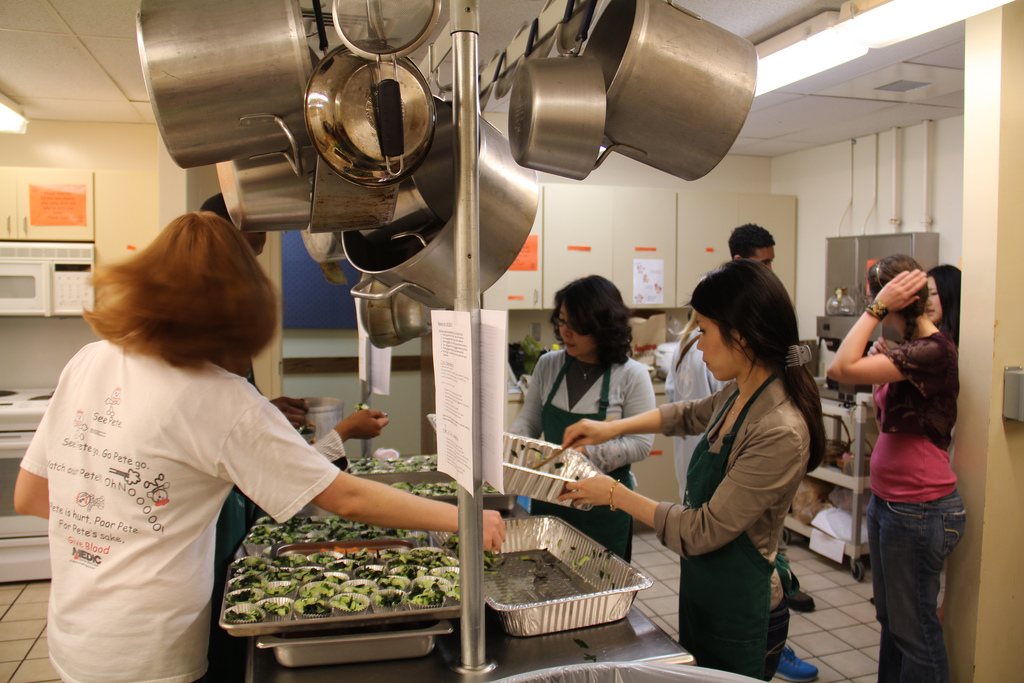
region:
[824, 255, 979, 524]
a Woman wearing a pink shirt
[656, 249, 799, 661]
A woman wearing an apron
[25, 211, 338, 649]
A woman wearing a white T-shirt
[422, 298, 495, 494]
directions on how to make lunch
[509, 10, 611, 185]
A pot hanging from the ceiling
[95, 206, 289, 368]
a woman with reddish hair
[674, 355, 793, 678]
Girl wearing an apron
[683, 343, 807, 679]
Girl is wearing an apron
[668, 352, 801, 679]
Girl wearing a green apron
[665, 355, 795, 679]
Girl is wearing a green apron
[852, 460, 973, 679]
Girl wearing pants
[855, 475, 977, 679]
Girl is wearing blue pants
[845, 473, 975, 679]
Girl wearing blue jeans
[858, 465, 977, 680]
Girl is wearing blue jeans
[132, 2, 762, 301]
pots hanging from the ceiling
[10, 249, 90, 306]
a white microwave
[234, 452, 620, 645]
food on the table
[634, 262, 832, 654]
a lady in a brown shirt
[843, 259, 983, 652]
a lady standing by the wall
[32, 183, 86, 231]
an orange paper on the wall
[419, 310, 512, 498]
papers hanging from the pole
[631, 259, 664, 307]
a white paper on the wall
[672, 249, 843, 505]
lady with long hair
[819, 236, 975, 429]
lady with hand on head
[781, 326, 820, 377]
a grey hair clip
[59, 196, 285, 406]
the hair is wild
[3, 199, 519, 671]
the person is wearing white shirt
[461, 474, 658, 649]
the pan is empty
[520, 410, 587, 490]
a spoon in a hand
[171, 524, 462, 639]
food in a pan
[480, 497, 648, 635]
Aluminum tin pan on the table.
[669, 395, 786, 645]
The lady is wearing a green apron.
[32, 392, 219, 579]
The shirt has writing on the back of it.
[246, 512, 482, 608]
Food on the cooking sheet.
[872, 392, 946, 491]
The shirt is red.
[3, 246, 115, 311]
A white microwave above the stove.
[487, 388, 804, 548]
The lady is stirring food in the pan.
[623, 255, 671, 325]
A white paper on the cabinet.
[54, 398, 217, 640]
The shirt is white.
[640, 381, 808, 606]
shirts is worn by human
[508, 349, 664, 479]
shirts is worn by human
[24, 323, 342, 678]
shirts is worn by human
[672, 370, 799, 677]
apron is worn by human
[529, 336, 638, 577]
apron is worn by human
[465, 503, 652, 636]
sheet pan rests on counter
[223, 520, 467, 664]
sheet pan rests on counter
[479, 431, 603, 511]
sheet pan is held by human